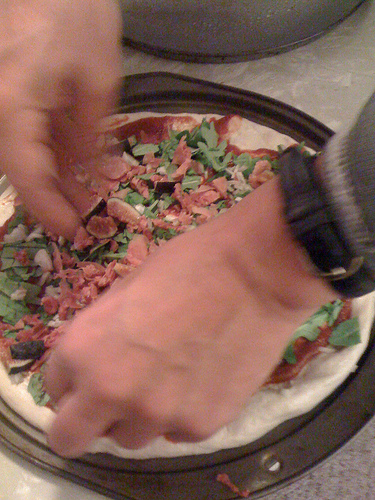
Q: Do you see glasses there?
A: No, there are no glasses.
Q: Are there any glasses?
A: No, there are no glasses.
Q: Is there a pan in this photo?
A: Yes, there is a pan.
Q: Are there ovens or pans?
A: Yes, there is a pan.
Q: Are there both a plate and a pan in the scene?
A: Yes, there are both a pan and a plate.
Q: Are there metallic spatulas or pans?
A: Yes, there is a metal pan.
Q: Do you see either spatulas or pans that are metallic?
A: Yes, the pan is metallic.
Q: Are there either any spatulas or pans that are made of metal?
A: Yes, the pan is made of metal.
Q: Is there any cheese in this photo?
A: No, there is no cheese.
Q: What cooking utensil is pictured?
A: The cooking utensil is a pan.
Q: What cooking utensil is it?
A: The cooking utensil is a pan.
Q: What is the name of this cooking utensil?
A: That is a pan.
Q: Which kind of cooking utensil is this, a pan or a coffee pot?
A: That is a pan.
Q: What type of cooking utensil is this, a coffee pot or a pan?
A: That is a pan.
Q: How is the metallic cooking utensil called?
A: The cooking utensil is a pan.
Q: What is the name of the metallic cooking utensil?
A: The cooking utensil is a pan.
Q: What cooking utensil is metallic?
A: The cooking utensil is a pan.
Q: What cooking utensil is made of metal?
A: The cooking utensil is a pan.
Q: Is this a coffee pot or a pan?
A: This is a pan.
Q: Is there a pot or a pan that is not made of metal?
A: No, there is a pan but it is made of metal.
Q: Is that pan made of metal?
A: Yes, the pan is made of metal.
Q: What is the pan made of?
A: The pan is made of metal.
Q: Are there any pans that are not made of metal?
A: No, there is a pan but it is made of metal.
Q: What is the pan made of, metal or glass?
A: The pan is made of metal.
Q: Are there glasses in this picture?
A: No, there are no glasses.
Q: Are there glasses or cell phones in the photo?
A: No, there are no glasses or cell phones.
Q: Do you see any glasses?
A: No, there are no glasses.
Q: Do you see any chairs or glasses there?
A: No, there are no glasses or chairs.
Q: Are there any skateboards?
A: No, there are no skateboards.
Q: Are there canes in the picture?
A: No, there are no canes.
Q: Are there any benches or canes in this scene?
A: No, there are no canes or benches.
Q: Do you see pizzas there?
A: Yes, there is a pizza.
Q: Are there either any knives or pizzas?
A: Yes, there is a pizza.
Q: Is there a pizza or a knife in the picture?
A: Yes, there is a pizza.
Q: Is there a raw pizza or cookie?
A: Yes, there is a raw pizza.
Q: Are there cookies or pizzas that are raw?
A: Yes, the pizza is raw.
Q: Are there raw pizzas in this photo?
A: Yes, there is a raw pizza.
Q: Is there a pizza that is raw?
A: Yes, there is a pizza that is raw.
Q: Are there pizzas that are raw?
A: Yes, there is a pizza that is raw.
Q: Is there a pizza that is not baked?
A: Yes, there is a raw pizza.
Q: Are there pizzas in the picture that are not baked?
A: Yes, there is a raw pizza.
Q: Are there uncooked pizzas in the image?
A: Yes, there is an uncooked pizza.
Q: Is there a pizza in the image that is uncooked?
A: Yes, there is a pizza that is uncooked.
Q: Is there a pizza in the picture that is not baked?
A: Yes, there is a uncooked pizza.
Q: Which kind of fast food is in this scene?
A: The fast food is a pizza.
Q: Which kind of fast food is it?
A: The food is a pizza.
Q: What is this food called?
A: This is a pizza.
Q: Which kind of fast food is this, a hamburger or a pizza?
A: This is a pizza.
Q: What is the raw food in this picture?
A: The food is a pizza.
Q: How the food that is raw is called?
A: The food is a pizza.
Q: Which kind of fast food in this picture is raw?
A: The fast food is a pizza.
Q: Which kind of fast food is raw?
A: The fast food is a pizza.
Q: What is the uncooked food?
A: The food is a pizza.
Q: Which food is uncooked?
A: The food is a pizza.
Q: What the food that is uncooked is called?
A: The food is a pizza.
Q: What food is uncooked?
A: The food is a pizza.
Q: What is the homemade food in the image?
A: The food is a pizza.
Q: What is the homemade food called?
A: The food is a pizza.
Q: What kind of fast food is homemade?
A: The fast food is a pizza.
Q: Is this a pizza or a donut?
A: This is a pizza.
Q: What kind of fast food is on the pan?
A: The food is a pizza.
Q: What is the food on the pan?
A: The food is a pizza.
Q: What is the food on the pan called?
A: The food is a pizza.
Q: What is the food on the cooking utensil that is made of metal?
A: The food is a pizza.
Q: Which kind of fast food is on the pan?
A: The food is a pizza.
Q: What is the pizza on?
A: The pizza is on the pan.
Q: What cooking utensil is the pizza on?
A: The pizza is on the pan.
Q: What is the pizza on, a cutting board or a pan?
A: The pizza is on a pan.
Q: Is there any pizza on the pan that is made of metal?
A: Yes, there is a pizza on the pan.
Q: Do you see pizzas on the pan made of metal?
A: Yes, there is a pizza on the pan.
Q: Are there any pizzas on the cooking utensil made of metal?
A: Yes, there is a pizza on the pan.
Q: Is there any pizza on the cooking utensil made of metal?
A: Yes, there is a pizza on the pan.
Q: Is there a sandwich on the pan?
A: No, there is a pizza on the pan.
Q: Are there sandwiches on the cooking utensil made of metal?
A: No, there is a pizza on the pan.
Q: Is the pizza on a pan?
A: Yes, the pizza is on a pan.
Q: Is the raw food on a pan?
A: Yes, the pizza is on a pan.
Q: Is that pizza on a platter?
A: No, the pizza is on a pan.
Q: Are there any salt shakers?
A: No, there are no salt shakers.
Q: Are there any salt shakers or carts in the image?
A: No, there are no salt shakers or carts.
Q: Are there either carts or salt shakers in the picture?
A: No, there are no salt shakers or carts.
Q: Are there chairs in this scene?
A: No, there are no chairs.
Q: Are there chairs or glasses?
A: No, there are no chairs or glasses.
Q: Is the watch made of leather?
A: Yes, the watch is made of leather.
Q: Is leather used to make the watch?
A: Yes, the watch is made of leather.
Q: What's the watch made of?
A: The watch is made of leather.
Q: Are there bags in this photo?
A: No, there are no bags.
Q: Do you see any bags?
A: No, there are no bags.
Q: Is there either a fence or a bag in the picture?
A: No, there are no bags or fences.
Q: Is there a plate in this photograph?
A: Yes, there is a plate.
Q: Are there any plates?
A: Yes, there is a plate.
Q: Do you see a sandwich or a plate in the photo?
A: Yes, there is a plate.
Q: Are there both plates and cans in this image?
A: No, there is a plate but no cans.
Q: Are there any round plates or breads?
A: Yes, there is a round plate.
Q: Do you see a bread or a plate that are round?
A: Yes, the plate is round.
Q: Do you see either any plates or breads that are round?
A: Yes, the plate is round.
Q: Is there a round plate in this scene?
A: Yes, there is a round plate.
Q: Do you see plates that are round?
A: Yes, there is a plate that is round.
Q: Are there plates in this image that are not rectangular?
A: Yes, there is a round plate.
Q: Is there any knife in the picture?
A: No, there are no knives.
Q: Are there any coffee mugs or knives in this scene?
A: No, there are no knives or coffee mugs.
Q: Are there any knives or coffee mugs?
A: No, there are no knives or coffee mugs.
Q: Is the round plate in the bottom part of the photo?
A: No, the plate is in the top of the image.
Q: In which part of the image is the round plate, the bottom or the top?
A: The plate is in the top of the image.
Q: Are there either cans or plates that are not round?
A: No, there is a plate but it is round.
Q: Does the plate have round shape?
A: Yes, the plate is round.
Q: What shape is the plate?
A: The plate is round.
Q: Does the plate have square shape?
A: No, the plate is round.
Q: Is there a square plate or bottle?
A: No, there is a plate but it is round.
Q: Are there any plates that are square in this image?
A: No, there is a plate but it is round.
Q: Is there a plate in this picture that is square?
A: No, there is a plate but it is round.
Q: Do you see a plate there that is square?
A: No, there is a plate but it is round.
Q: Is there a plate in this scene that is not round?
A: No, there is a plate but it is round.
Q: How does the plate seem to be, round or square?
A: The plate is round.